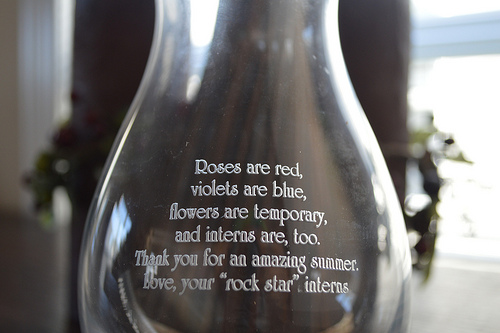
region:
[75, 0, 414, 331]
clear vase with writing on it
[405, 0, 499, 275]
window with white frame in background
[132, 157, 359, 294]
poem etched in white on side of vase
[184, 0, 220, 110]
reflection of light through the vase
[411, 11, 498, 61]
horizontal white frame on window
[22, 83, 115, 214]
plant in the background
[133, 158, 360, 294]
writing on vase is etched in white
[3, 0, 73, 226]
window with blinds closed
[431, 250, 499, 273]
white window sill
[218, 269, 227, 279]
quotation marks etched in vase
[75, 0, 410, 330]
Glass vase with a poem on the side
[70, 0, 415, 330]
Glass with a poem on the side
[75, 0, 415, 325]
Glass with words inscribed on the side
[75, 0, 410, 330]
Glass with an inscription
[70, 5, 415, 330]
Glass with a poem inscribed on it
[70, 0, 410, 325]
Vase with a poem inscribed on the side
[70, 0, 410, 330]
Vase inscribed with a thank you message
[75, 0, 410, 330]
Inscribed poem on a glass vase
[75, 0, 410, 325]
Glass inscription thank you gift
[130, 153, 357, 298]
Poem on the side of glass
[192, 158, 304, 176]
"Roses are red" written on glass vase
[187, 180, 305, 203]
"violets are blue" written on vase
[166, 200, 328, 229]
"flowers are temporary" written on a vase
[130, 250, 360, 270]
"Thank you for an amazing summer" written on vase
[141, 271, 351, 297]
"Love, your "rock star" interns" written on vase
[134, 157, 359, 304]
poem written on vase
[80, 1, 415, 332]
clear glass vase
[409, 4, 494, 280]
window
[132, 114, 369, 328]
Scripture on a glass vase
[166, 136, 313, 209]
Scripture on a glass vase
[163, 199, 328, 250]
Scripture on a glass vase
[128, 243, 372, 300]
Scripture on a glass vase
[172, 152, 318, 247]
Scripture on a glass vase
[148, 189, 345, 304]
Scripture on a glass vase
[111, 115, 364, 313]
Scripture on a glass vase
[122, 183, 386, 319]
Scripture on a glass vase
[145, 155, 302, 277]
Scripture on a glass vase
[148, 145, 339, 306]
Scripture on a glass vase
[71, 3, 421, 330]
clear glass vase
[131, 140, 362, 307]
white writing on the vase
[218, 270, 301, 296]
two words in quotation marks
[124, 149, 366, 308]
poem on the side of the vase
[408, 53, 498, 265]
light coming in the window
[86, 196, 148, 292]
reflection on the glass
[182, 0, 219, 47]
light glare on the glass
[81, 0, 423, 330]
the vase becomes skinnier at the top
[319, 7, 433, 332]
side of the vase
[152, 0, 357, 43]
neck of the vase